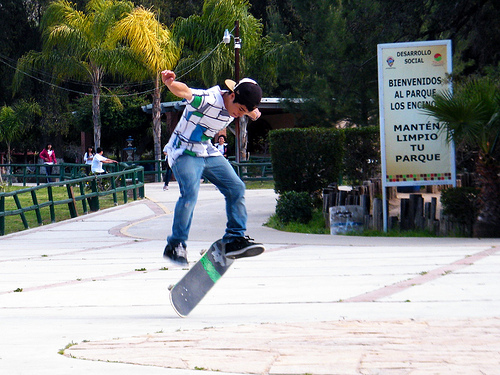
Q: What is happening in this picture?
A: A man is doing a trick with his skateboard.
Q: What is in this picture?
A: A man, skateboard, and a park.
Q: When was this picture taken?
A: During the day.